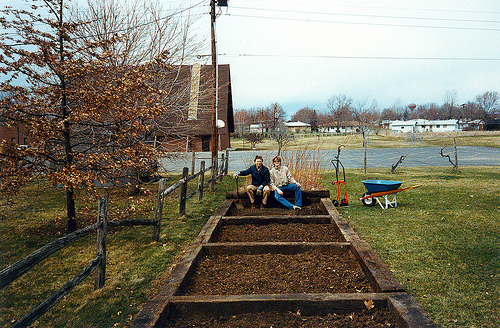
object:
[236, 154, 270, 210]
person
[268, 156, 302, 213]
boy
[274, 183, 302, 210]
pant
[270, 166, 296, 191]
shirt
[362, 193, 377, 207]
wheel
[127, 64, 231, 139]
roof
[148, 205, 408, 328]
court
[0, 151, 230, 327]
fence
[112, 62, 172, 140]
leave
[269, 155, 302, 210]
people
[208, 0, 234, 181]
post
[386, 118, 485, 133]
building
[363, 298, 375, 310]
leaf